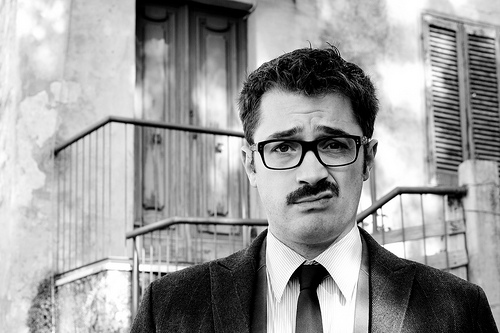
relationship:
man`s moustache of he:
[286, 180, 339, 205] [133, 48, 500, 333]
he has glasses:
[133, 48, 500, 333] [243, 126, 369, 172]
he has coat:
[133, 48, 500, 333] [129, 225, 500, 333]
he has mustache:
[133, 48, 500, 333] [279, 180, 343, 209]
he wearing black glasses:
[133, 48, 500, 333] [249, 132, 369, 169]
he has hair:
[133, 48, 500, 333] [283, 176, 348, 198]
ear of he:
[211, 129, 273, 194] [133, 48, 500, 333]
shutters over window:
[423, 6, 498, 197] [417, 8, 499, 189]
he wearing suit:
[133, 48, 500, 333] [132, 229, 495, 331]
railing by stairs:
[363, 182, 478, 277] [381, 217, 469, 267]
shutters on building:
[423, 10, 500, 186] [3, 7, 494, 260]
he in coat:
[133, 48, 500, 333] [129, 256, 494, 331]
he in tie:
[133, 48, 500, 333] [291, 263, 333, 330]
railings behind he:
[46, 112, 475, 300] [133, 48, 500, 333]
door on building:
[186, 0, 250, 261] [13, 0, 497, 333]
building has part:
[13, 5, 232, 251] [44, 58, 98, 99]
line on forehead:
[293, 105, 320, 115] [252, 89, 397, 137]